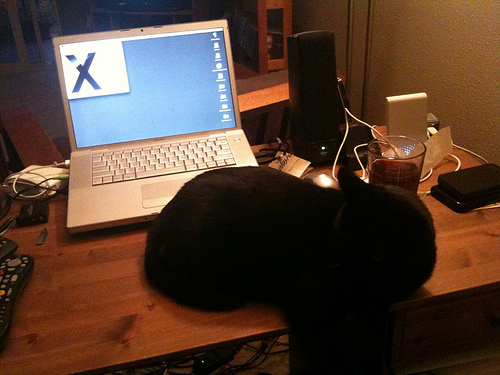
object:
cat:
[143, 164, 436, 326]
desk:
[0, 125, 499, 374]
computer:
[53, 18, 258, 234]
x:
[65, 52, 102, 93]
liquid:
[367, 158, 426, 194]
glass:
[365, 135, 428, 193]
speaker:
[152, 25, 164, 29]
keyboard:
[89, 135, 237, 186]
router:
[3, 162, 71, 201]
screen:
[57, 26, 237, 148]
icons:
[210, 31, 232, 123]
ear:
[336, 163, 369, 199]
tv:
[101, 6, 186, 14]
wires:
[0, 177, 67, 219]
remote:
[0, 252, 36, 339]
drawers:
[400, 287, 499, 327]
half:
[368, 158, 429, 193]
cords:
[219, 338, 279, 373]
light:
[319, 145, 327, 150]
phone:
[0, 183, 13, 195]